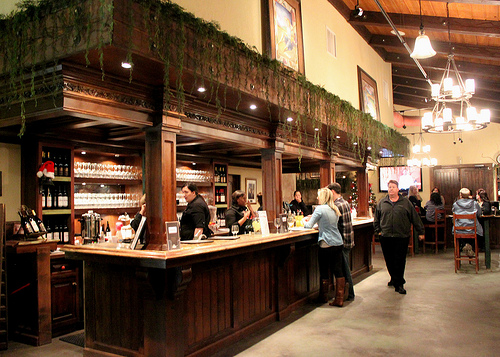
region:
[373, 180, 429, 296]
man in a gray shirt and black pants walking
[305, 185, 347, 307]
woman in a blue shirt and brown boots standing at the bar.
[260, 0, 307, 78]
Large framed picture hanging on the wall.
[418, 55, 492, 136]
Large chandelier hanging from the ceiling.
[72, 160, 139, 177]
Upside down glasses on a shelf behind the bar.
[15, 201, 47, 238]
Three bottles of wine on display.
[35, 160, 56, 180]
A red and white Santa hat hanging behind the bar.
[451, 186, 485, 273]
Person in a blue coat sitting on a wooden bar chair.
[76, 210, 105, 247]
A chrome coffee urn sitting on the back of the bar.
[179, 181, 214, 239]
Bartender in a black shirt talking to another bartender.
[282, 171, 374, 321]
a couple at a wine bar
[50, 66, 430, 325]
a fancy wine bar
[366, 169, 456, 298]
a man in black pants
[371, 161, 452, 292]
a hefty man wearing a black jacket and pants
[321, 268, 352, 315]
knee high leather boots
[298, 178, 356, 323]
a woman in a denim shirt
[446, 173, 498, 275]
a couple sitting at a table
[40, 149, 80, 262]
bottles of wine on a shelf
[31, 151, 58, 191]
a Santa hat decorating the bar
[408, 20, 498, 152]
hanging iron light fixtures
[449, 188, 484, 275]
Person in blue top seating in chair.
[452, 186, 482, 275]
Blonde person sitting in brown chair.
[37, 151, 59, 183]
Santa hat hanging from shelf.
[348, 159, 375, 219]
Christmas tree behind wood banister.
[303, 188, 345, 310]
Blonde woman standing at bar.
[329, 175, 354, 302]
Person in plaid shirt standing at bar.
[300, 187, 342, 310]
Woman in blue shirt and boots standing at bar.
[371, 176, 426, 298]
Large man in black walking in front of bar.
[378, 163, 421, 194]
Flat screen television hanging on wall.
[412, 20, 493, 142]
White lights hanging from ceiling.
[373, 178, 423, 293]
man in dark pants walking by bar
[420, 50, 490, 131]
ceiling candelabra by the man walking by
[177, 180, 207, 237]
heavyset person in black behind the bar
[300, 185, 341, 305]
woman with long blond hair standing at the bar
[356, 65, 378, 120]
picture over the bar by the man walking by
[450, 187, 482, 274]
man in light blue hoodie sitting in brown chair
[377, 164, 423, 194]
framed picture on far wall of the bar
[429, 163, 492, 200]
wood door at far end of bar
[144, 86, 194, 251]
wood column on bar in foreground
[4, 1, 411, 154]
top of bar with green plants hanging down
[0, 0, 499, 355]
a bar and grill restaurant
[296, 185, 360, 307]
two people standing at the bar waiting to be served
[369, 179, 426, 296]
a man walking past a bar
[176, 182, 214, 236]
a bartender behind a bar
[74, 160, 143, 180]
glasses on a shelf at a bar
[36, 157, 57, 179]
a small santa claus hat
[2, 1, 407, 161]
decorative ferns on the top of a bar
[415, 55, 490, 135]
a chandelier hanging from the ceiling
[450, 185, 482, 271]
a person sitting in a chair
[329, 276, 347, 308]
a woman's cowboy boot